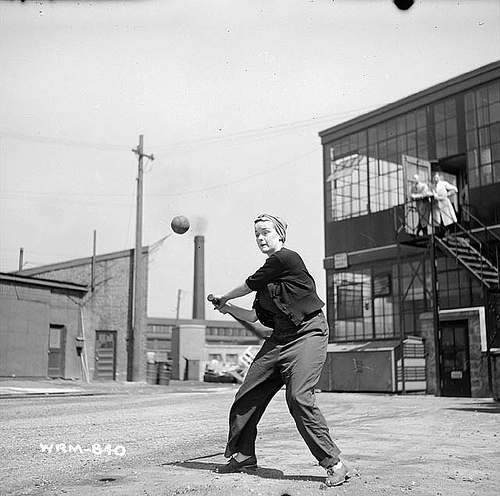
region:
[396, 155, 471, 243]
The men are watching the woman.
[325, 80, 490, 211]
The building has large glass windows.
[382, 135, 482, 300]
The men are standing on a staircase.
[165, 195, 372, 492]
The woman is playing a game.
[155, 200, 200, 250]
A ball.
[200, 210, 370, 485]
The woman has a bat in her hands.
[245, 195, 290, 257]
The woman is covering her hair with a bandana.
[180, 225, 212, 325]
A smokestack.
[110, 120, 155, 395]
A utility pole.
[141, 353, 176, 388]
Steel barrels.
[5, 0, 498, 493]
Black and white photo of woman swinging at a softball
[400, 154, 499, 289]
Black and white photo of two men watching a woman hit a softball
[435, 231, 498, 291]
Metal ladder outside building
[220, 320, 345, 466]
Black and white photo of woman wearing pants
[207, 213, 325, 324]
Woman swinging right-handed at a softball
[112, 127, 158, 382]
Black and white photo of electrical post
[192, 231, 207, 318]
Black and white photo of a smokestack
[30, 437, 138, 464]
Black and white photo with white writing of WRM-840 on it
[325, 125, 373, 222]
Black and white photo of window open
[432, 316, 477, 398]
Black and white photo of black door into building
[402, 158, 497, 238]
Two men in white coats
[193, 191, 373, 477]
Middle aged lady with a bat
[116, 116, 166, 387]
Tall wooden telephone poll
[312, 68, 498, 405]
Large building with lot of windows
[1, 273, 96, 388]
Brick building with single door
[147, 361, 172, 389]
Two metal barrels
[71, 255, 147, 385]
Brick building with front door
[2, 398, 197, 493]
Gravel paved parking lot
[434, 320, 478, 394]
Black door with four windows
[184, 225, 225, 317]
Plant chimney for carbon emissions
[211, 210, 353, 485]
woman swinging at a ball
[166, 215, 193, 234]
softball sized ball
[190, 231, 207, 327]
dark tall smokestack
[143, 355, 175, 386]
two barrels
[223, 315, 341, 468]
dark pants on a woman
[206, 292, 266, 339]
baseball bat swung by a woman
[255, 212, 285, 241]
beige head covering on a woman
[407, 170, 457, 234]
two people watching woman swing bat at ball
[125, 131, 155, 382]
very tall telephone pole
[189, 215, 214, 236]
smoke coming from a tall smokestack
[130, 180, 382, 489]
Playing with bat and ball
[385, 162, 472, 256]
The boy has fans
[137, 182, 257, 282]
The ball is in the air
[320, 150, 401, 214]
don't break a window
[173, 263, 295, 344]
he is hurting his arms holding the bat like that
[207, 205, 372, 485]
It is cold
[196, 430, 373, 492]
Not wearing cleats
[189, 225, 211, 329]
factories near by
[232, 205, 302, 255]
he is making a funny face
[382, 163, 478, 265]
Those people better not fall